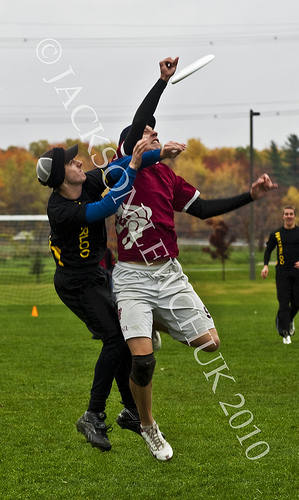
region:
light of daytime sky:
[2, 1, 297, 149]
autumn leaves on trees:
[1, 132, 297, 241]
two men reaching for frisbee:
[36, 53, 277, 459]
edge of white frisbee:
[170, 53, 214, 83]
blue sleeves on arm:
[86, 139, 187, 222]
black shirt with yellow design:
[47, 164, 110, 270]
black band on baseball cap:
[36, 143, 78, 188]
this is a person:
[22, 127, 142, 458]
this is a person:
[102, 44, 277, 459]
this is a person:
[250, 186, 297, 354]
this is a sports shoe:
[65, 399, 115, 461]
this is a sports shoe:
[111, 404, 169, 444]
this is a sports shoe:
[143, 423, 180, 471]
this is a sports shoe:
[276, 326, 295, 353]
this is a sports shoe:
[279, 313, 296, 336]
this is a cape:
[22, 136, 90, 198]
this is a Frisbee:
[165, 42, 218, 100]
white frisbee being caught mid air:
[168, 53, 213, 91]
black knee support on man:
[131, 349, 160, 389]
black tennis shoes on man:
[73, 408, 159, 448]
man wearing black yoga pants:
[56, 280, 145, 415]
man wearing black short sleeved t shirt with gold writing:
[40, 168, 110, 264]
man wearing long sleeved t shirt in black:
[112, 147, 248, 261]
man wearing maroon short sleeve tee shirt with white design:
[119, 144, 203, 259]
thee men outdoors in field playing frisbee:
[36, 50, 298, 460]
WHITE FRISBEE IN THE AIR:
[176, 50, 214, 81]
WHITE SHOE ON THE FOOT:
[142, 425, 166, 458]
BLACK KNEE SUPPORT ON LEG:
[136, 353, 157, 381]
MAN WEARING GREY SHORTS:
[140, 270, 162, 301]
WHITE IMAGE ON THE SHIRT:
[119, 201, 152, 253]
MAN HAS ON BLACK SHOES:
[79, 411, 111, 444]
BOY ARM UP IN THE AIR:
[139, 51, 174, 126]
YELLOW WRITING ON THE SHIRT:
[79, 232, 90, 257]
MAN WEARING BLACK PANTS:
[87, 285, 100, 310]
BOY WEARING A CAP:
[40, 144, 61, 185]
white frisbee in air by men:
[168, 50, 215, 84]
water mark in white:
[24, 33, 279, 460]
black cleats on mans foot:
[71, 409, 118, 455]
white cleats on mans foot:
[139, 420, 177, 462]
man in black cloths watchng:
[257, 206, 298, 346]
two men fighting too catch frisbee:
[37, 53, 284, 467]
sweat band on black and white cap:
[30, 143, 87, 193]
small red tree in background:
[200, 214, 241, 288]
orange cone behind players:
[27, 303, 42, 320]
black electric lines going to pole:
[199, 113, 259, 123]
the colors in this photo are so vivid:
[9, 51, 297, 490]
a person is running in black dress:
[259, 203, 297, 343]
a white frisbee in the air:
[149, 43, 213, 89]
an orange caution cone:
[27, 302, 45, 317]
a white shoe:
[145, 420, 169, 448]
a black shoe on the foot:
[70, 404, 115, 447]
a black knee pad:
[123, 346, 148, 396]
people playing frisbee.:
[41, 44, 298, 484]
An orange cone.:
[30, 299, 39, 319]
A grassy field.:
[2, 241, 295, 499]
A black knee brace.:
[131, 352, 158, 385]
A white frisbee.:
[170, 53, 214, 83]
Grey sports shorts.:
[114, 261, 213, 345]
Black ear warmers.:
[49, 143, 66, 189]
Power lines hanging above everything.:
[0, 34, 297, 125]